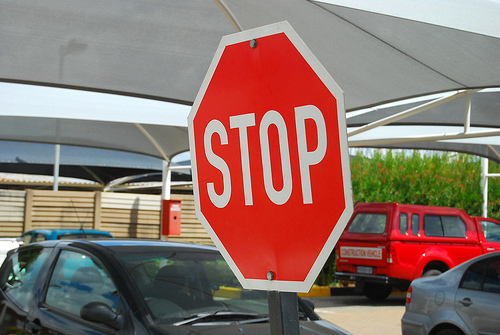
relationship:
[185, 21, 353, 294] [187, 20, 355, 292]
border around stop sign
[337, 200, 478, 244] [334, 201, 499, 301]
camper shell on back of truck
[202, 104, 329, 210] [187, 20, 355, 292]
letters on front of stop sign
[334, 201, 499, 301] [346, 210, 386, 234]
truck has back window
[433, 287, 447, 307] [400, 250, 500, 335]
gas tank door on side of vehicles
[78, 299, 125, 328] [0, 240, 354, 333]
side mirror on side of car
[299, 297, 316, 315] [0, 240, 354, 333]
side mirror on side of car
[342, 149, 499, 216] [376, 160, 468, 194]
hedges have flowers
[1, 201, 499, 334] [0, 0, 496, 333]
vehicles parked in a lot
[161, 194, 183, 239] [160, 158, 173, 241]
box attached to pole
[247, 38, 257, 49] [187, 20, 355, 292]
bolt on top of stop sign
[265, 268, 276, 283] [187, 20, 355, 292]
bolt on top of stop sign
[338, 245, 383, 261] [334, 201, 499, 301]
sign on back of truck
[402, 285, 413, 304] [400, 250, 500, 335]
brake light on back of vehicles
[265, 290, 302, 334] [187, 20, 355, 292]
pole holding up stop sign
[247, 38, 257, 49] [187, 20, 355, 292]
bolt on front of stop sign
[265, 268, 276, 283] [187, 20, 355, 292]
bolt on front of stop sign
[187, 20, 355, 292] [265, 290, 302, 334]
stop sign on top of pole